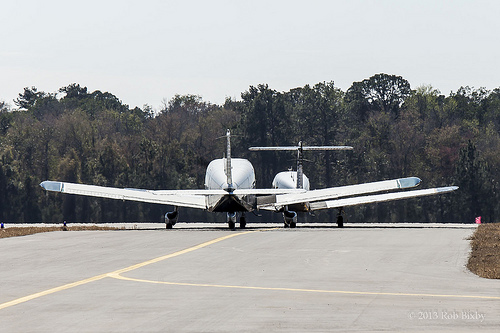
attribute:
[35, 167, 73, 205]
tip — blue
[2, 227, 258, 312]
line — yellow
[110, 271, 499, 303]
line — yellow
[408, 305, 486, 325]
lettering — white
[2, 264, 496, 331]
lines — yellow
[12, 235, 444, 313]
lines — yellow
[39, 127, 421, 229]
plane — white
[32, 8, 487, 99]
sky — blue, clear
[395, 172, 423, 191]
tip — blue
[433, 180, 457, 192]
tip — blue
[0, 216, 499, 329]
ground — gray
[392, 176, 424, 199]
tip — blue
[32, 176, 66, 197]
tip — blue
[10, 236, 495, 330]
lines — yellow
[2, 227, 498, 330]
runway — pavement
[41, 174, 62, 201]
tip — blue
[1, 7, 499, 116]
sky — blue